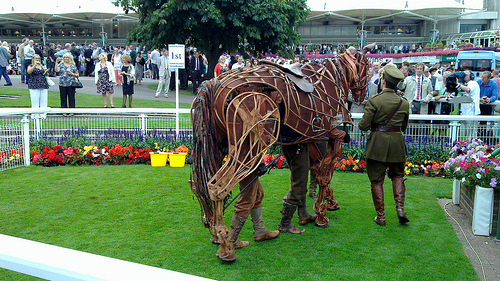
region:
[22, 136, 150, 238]
the grass is green and visible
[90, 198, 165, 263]
the grass is green and visible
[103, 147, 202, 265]
the grass is green and visible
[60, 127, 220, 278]
the grass is green and visible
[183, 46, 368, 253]
brown metal horse costume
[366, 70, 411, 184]
green polyester military uniform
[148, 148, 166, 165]
yellow bucket on ground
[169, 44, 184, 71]
green and white sign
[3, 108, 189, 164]
white metal barrier fence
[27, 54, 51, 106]
woman taking picture in park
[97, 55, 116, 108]
woman wearing floral dress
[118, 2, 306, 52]
tree with green leaves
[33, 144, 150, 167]
flowers next to white fence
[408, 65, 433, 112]
man wearing trench coat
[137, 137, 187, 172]
the buckets are yellow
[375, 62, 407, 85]
the hat is green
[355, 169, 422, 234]
the man is wearing boots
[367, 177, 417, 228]
the boots are brown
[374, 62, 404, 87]
the man is wearing a hat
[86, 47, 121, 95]
the woman is wearing a sweater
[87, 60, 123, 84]
the sweater is white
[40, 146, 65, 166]
the flowers are red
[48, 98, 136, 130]
the rail is white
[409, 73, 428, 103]
the tie is red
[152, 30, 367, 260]
men in a horse costume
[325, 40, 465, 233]
man in uniform leading horse costume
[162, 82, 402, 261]
legs of two men in the horse costume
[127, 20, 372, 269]
horse costumed standing in the grass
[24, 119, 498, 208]
colorful flowers along the edge of the show area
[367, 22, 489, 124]
man taking picture of horse costume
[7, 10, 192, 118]
crowd of people around the horse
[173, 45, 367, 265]
mechanical saddle on the horse costume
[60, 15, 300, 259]
1st sign in front of horse exhibition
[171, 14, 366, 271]
wire horse costume sculpture in a grass enclosure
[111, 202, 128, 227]
Small patch of green grass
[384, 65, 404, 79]
Green hat of horse rider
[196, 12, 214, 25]
Green leaf on the tree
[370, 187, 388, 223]
Left brown boot of horseback rider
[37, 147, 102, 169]
A group of red, pink, yellow, and white flowers in garden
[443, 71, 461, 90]
Large black camera being used by camera man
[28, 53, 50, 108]
Female taking a picture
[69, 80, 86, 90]
Black purse of female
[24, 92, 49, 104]
White pants of female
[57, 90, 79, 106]
Black pants of female